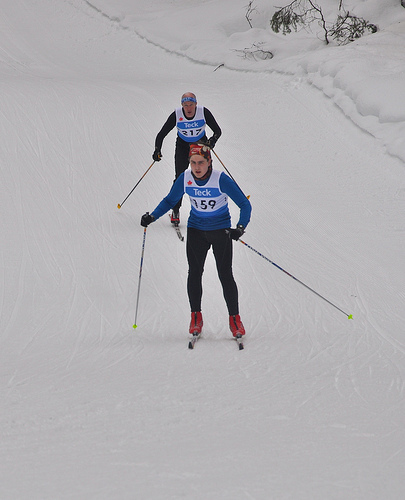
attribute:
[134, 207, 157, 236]
glove — black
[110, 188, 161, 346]
pole — yellow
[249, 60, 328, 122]
snow — white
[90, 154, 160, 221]
pole — orange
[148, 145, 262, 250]
shirt — blue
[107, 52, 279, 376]
competitors — ski, skiing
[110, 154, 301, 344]
competitor — skiing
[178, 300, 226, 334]
boot — red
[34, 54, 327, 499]
sport — skiing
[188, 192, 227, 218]
bib — white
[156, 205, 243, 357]
pants — blue